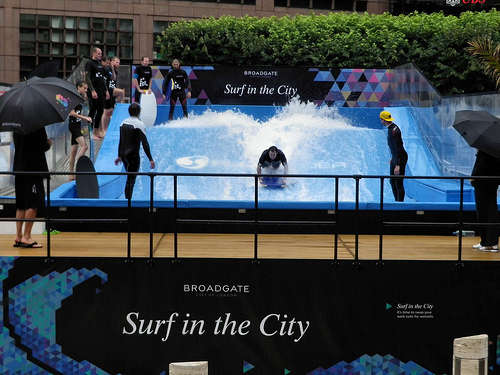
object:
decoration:
[314, 67, 391, 107]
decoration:
[0, 269, 109, 375]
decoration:
[302, 354, 443, 375]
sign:
[131, 63, 389, 107]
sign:
[0, 258, 500, 375]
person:
[114, 103, 155, 199]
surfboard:
[139, 90, 158, 127]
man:
[132, 56, 153, 104]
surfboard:
[261, 177, 286, 187]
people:
[162, 58, 192, 121]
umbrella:
[451, 110, 499, 159]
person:
[69, 82, 93, 181]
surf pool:
[57, 105, 422, 201]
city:
[0, 0, 500, 375]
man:
[257, 146, 289, 185]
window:
[66, 29, 77, 42]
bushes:
[155, 10, 500, 98]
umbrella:
[1, 76, 86, 133]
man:
[13, 126, 53, 248]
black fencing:
[0, 170, 499, 270]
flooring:
[0, 232, 500, 261]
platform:
[0, 171, 500, 375]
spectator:
[84, 46, 110, 138]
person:
[379, 111, 409, 203]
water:
[146, 95, 382, 202]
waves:
[267, 96, 350, 128]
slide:
[127, 126, 398, 200]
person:
[112, 57, 121, 87]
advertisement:
[121, 313, 312, 344]